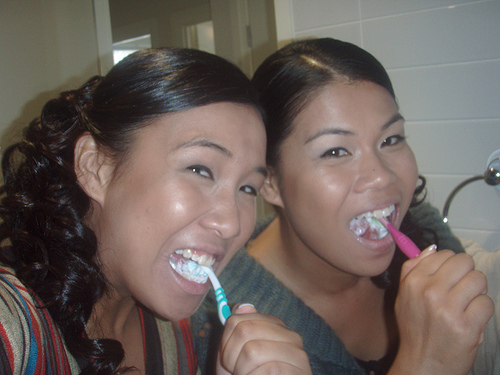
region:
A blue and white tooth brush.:
[196, 254, 239, 334]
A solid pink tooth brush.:
[371, 201, 421, 278]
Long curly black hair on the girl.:
[2, 57, 136, 364]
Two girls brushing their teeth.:
[3, 28, 472, 368]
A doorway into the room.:
[91, 0, 280, 92]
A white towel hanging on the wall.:
[440, 227, 498, 374]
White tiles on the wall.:
[271, 1, 497, 288]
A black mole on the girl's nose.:
[356, 157, 392, 192]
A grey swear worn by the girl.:
[180, 186, 479, 371]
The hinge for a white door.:
[233, 16, 260, 56]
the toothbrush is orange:
[358, 206, 443, 264]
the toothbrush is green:
[179, 276, 254, 323]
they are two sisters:
[108, 118, 452, 334]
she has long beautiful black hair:
[21, 139, 83, 330]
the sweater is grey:
[246, 276, 331, 336]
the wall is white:
[428, 105, 483, 163]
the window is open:
[103, 13, 268, 35]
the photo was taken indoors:
[3, 5, 490, 367]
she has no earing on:
[15, 95, 118, 229]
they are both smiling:
[148, 131, 453, 330]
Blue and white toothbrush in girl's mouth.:
[205, 271, 232, 321]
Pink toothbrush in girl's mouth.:
[378, 216, 416, 256]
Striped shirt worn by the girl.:
[3, 270, 201, 374]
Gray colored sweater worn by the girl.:
[226, 251, 466, 374]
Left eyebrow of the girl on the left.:
[175, 133, 237, 158]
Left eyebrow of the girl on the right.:
[301, 130, 358, 140]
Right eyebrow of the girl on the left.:
[249, 160, 274, 180]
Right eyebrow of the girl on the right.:
[381, 117, 405, 130]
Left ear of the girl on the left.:
[77, 127, 110, 208]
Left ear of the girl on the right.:
[266, 160, 281, 205]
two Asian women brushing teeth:
[20, 22, 464, 351]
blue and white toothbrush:
[195, 270, 235, 327]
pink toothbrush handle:
[382, 222, 421, 260]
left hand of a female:
[387, 245, 498, 367]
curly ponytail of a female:
[7, 96, 85, 343]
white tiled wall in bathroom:
[411, 6, 493, 141]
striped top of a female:
[3, 269, 61, 372]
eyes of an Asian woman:
[172, 157, 269, 201]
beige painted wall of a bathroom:
[7, 5, 92, 82]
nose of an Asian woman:
[352, 157, 408, 194]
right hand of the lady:
[421, 280, 478, 333]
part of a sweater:
[298, 322, 331, 347]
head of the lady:
[219, 127, 254, 168]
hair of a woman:
[35, 250, 99, 347]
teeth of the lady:
[184, 251, 214, 282]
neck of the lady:
[318, 280, 357, 301]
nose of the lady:
[354, 165, 396, 200]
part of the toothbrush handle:
[396, 233, 411, 250]